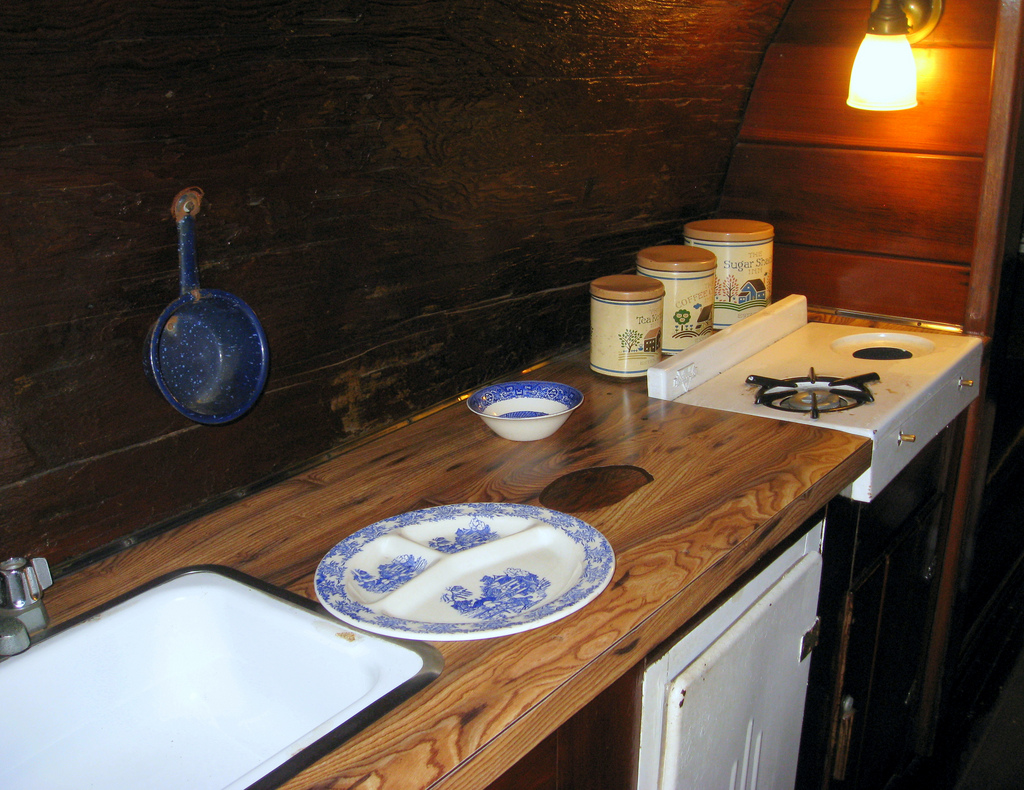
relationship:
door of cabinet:
[647, 548, 812, 784] [495, 400, 976, 781]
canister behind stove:
[590, 274, 666, 377] [645, 292, 984, 506]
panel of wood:
[719, 141, 988, 256] [748, 112, 1006, 361]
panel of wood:
[734, 245, 987, 325] [767, 94, 1016, 384]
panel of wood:
[737, 38, 998, 157] [733, 125, 1021, 387]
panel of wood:
[789, 4, 999, 44] [781, 82, 989, 383]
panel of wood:
[983, 444, 1019, 581] [789, 155, 993, 300]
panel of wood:
[959, 602, 1017, 727] [798, 138, 1006, 420]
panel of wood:
[990, 264, 1010, 405] [767, 94, 1016, 384]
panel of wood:
[0, 0, 787, 584] [755, 71, 1006, 326]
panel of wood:
[54, 68, 743, 152] [783, 107, 961, 356]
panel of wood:
[0, 0, 787, 584] [742, 95, 1021, 327]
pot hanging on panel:
[150, 181, 268, 420] [0, 0, 787, 584]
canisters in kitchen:
[589, 198, 771, 375] [611, 267, 756, 546]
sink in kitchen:
[5, 538, 436, 786] [78, 459, 742, 790]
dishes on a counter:
[314, 378, 622, 638] [411, 630, 623, 790]